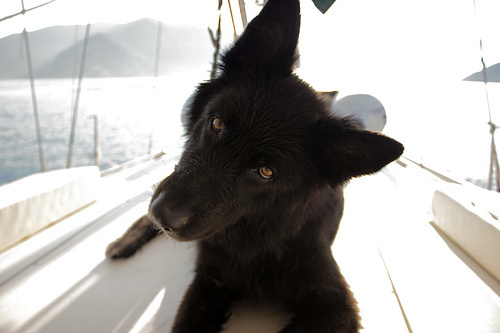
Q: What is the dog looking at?
A: The camera.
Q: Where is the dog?
A: On a boat.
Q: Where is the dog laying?
A: On a white surface.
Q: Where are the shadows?
A: The right of the dog.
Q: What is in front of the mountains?
A: Water.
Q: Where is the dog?
A: On a boat.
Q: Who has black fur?
A: The dog.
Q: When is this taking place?
A: Daytime.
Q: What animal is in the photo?
A: Dog.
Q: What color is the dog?
A: Black.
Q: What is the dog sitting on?
A: Boat.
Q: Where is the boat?
A: Water.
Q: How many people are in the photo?
A: None.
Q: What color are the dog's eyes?
A: Brown.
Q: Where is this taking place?
A: On a boat.